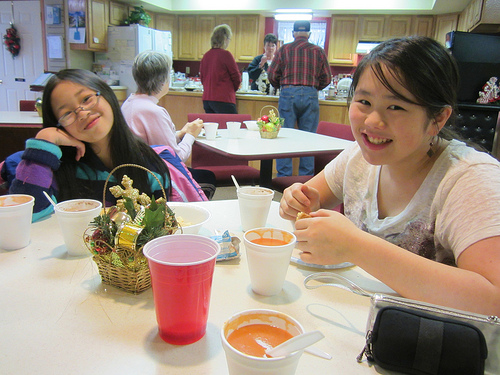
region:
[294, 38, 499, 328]
this is a person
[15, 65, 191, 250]
this is a person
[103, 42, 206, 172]
this is a person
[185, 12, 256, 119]
this is a person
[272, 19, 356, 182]
this is a person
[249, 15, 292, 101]
this is a person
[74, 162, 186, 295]
a basket of flowers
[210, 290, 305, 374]
this is a cup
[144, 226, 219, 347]
this is a cup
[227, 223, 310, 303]
this is a cup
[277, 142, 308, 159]
edge of a table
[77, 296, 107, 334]
part of a table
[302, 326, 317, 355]
part of a handle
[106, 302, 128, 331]
part of a shade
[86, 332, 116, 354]
part of a table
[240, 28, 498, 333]
a young Asian girl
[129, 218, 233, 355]
a red solo cup.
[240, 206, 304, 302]
a foam cup with orange liquid.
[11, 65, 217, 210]
a young Asian girl.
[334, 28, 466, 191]
a girl with dark hair.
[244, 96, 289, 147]
a basket of fruit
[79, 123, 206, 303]
a basket on a table.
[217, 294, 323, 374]
a bowl of ice cream.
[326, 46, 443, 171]
a woman smiling.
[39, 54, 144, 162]
a girl in glasses.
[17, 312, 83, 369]
this is a table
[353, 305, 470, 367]
this is a bag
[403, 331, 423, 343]
the bag is black in color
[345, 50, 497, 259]
this is a lady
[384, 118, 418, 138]
the lady is brown in color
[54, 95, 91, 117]
this is a spectacle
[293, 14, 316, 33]
this is a cap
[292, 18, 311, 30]
the cap is blue in color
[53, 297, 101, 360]
the table is white in color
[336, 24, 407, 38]
this is the wall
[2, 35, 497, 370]
two girls sitting at a table and smiling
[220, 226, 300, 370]
orange liquid in Styrofoam cups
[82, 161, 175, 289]
centerpiece in a small basket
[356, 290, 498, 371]
black case in front of silver purse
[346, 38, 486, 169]
girl's dark hair is parted and pulled back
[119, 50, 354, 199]
woman sitting at a table with two empty chairs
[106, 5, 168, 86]
plant on top of a refrigerator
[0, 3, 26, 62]
seasonal decoration hung on door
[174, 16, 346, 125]
man and woman standing at counter are seen from behind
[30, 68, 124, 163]
girl's tilted head leaning on her hand